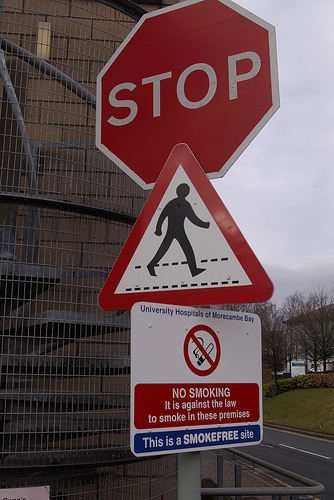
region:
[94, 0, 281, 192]
a red stop sign.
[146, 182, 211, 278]
a figure of a human.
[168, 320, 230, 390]
a no smoking sign.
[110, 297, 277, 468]
a no smoking sign.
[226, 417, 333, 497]
a section of a road.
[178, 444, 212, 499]
a sign post.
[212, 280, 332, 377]
a forest of leafless tree.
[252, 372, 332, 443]
a field of green grass.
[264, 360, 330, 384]
a parking lot of parked cars.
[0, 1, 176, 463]
a tall multi story building.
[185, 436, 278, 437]
word smokefree is written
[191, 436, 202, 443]
word smokefree is written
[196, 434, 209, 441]
word smokefree is written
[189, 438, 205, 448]
word smokefree is written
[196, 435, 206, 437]
word smokefree is written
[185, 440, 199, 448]
word smokefree is written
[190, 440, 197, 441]
word smokefree is written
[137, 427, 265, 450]
smoke free site sign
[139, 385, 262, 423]
no smoking sign on post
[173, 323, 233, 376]
no smoking picture on sign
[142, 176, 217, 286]
pedestrian crossing road sign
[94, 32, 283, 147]
red and white stop sign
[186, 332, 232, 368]
cigarette with a line through it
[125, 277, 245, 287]
dotted line on the bottom of a sign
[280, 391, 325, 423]
green grass by street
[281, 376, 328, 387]
bushes by green grass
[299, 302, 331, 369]
trees with no leaves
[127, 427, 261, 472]
blue and white sign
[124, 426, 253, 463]
sign that says this is a smoke free site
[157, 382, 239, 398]
white letters that spell no smoking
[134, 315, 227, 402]
no smoking sign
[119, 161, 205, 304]
a walk sign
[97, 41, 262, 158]
white letters that spell stop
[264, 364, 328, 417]
green and brown bushes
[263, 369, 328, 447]
green and brown bushes on a hill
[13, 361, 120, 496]
a caged building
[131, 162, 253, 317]
caution sign on a pole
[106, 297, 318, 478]
no smoking sign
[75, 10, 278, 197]
red stop sign on a pole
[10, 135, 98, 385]
spiral stair case with a gate around it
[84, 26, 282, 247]
red signs on a pole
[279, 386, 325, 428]
green grass on a hill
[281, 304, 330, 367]
dead trees near grass hill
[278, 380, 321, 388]
green bush on a hill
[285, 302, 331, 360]
building behind some trees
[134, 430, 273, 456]
blue text on a sign